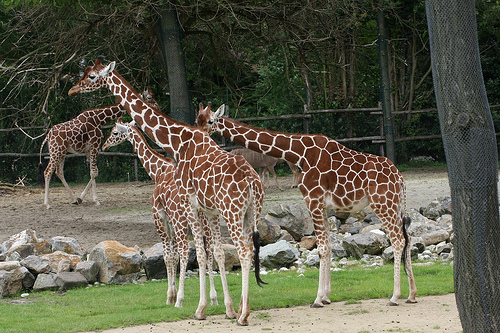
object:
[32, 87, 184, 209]
giraffe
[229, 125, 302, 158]
neck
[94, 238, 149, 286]
rocks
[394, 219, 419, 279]
tail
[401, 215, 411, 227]
tuft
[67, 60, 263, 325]
giraffe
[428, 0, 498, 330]
tree trunk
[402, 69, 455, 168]
fence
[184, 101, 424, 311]
giraffes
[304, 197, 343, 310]
leg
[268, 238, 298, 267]
rocks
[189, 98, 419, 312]
giraffe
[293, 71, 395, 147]
fence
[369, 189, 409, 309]
leg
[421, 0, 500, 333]
trunk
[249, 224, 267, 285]
tail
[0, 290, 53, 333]
grass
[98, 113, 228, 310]
giraffe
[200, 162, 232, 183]
spots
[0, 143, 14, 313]
left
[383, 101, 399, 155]
sticks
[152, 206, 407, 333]
standing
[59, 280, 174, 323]
grass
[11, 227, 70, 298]
piled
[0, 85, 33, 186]
background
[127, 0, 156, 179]
tree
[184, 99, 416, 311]
group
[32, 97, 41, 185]
tree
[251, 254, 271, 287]
hair